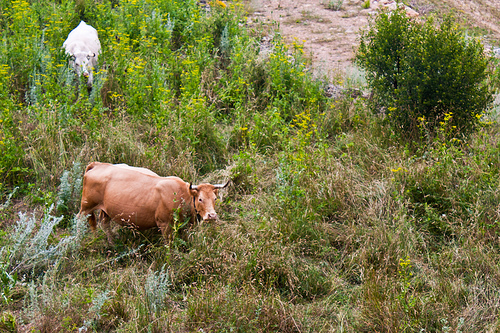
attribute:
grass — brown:
[89, 138, 487, 331]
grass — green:
[12, 145, 497, 330]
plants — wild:
[4, 205, 67, 275]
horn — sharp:
[188, 175, 198, 190]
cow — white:
[79, 165, 225, 240]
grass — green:
[224, 153, 401, 273]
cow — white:
[62, 20, 101, 92]